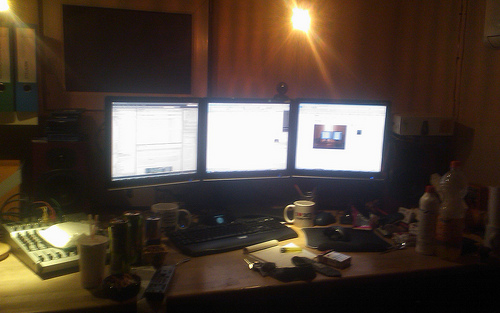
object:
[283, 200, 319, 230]
mug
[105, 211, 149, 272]
cans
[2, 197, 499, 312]
desk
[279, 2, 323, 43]
light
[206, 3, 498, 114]
wall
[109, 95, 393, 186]
monitors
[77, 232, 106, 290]
cup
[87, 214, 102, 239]
straw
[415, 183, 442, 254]
spray can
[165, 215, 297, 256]
keyboard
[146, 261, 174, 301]
remote control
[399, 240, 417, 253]
sunglasses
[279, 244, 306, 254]
lighter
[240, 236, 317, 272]
writing pad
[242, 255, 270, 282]
keys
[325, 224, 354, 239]
mouse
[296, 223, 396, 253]
pad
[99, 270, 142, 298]
ashtray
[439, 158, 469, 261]
bottle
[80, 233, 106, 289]
mixer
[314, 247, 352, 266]
cigarrettes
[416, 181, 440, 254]
cleaning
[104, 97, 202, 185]
monitor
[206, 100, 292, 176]
monitor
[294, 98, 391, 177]
monitor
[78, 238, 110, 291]
coffee